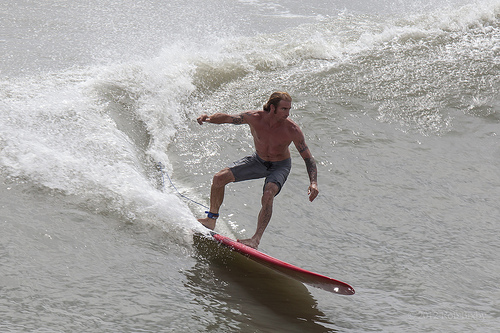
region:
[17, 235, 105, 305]
this is the water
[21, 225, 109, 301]
the water has ripples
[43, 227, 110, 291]
the ripples are big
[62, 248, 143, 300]
the water is blue in color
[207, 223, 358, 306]
this is a surfboard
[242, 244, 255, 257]
the surfboard is wooden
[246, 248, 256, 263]
the surfboard is red in color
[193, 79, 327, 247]
this is a man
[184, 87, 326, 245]
the man is on the surfboard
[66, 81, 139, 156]
the water has a wave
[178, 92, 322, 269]
surfer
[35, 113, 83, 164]
white and green ocean waves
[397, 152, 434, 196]
white and green ocean waves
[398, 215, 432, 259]
white and green ocean waves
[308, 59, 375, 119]
white and green ocean waves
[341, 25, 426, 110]
white and green ocean waves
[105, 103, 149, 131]
white and green ocean waves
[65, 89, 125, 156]
white and green ocean waves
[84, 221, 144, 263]
white and green ocean waves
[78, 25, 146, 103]
white and green ocean waves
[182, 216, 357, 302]
Man on a board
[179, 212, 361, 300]
Man is on a board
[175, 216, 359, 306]
Man on a red board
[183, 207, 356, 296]
Man is on a red board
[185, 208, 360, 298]
Man on a surfboard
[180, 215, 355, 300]
Man is on a surfboard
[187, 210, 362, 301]
Man on a red surfboard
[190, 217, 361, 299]
Man is on a red surfboard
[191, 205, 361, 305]
Surfboard attached to man's ankle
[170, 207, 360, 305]
Red surfboard attached to man's ankle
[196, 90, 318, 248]
the man on the surfboard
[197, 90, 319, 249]
the man standing on the surfboard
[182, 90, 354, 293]
the man riding a wave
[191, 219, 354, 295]
the surfboard under the man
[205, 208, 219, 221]
the band around the man's leg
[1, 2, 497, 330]
the body of water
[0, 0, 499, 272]
the small wave in the ocean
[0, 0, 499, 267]
the water splashing up from the wave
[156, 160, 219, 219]
the blue cord attached the band on the man's leg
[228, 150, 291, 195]
the swim shorts on the man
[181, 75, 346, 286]
surfer on red board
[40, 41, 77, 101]
white and green ocean waves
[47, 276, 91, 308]
white and green ocean waves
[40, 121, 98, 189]
white and green ocean waves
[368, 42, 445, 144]
white and green ocean waves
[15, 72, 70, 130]
white and green ocean waves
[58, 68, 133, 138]
white and green ocean waves